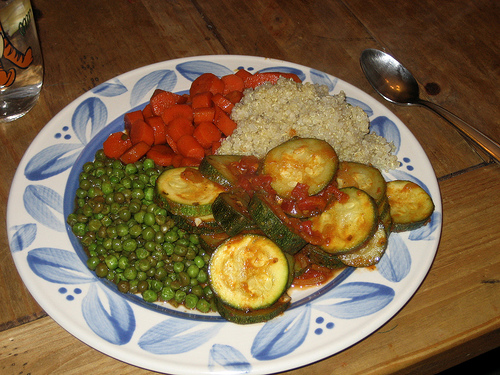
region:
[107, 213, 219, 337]
the peas are green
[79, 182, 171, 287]
the peas are green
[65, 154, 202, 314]
the peas are green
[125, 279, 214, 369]
the peas are green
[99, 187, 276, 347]
the peas are green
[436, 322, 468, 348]
edge of a table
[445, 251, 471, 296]
part of a table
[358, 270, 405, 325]
edge of a plate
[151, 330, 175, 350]
part of a plate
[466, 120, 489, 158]
part of a handle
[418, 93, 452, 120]
part of a spoon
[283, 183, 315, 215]
part of some tomato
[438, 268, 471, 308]
part of a table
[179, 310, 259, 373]
the plate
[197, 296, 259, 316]
the plate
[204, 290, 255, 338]
the plate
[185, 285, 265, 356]
the plate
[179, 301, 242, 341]
the plate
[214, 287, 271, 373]
the plate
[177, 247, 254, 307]
the plate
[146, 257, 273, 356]
the plate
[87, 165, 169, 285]
Green peas on plate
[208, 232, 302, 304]
Cut up zucchini on plate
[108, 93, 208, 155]
Cut up carrot on plate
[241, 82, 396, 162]
Brown grain rice on plate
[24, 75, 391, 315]
Blue floral pattern on white plate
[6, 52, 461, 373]
Blue and white plate on wooden table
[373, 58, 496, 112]
Metal spoon on wood table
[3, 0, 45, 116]
Glass jar with Tigger on it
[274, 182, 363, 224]
Cut up tomato sauce on zucchini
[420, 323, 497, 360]
Edge of wooden table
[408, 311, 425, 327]
the table is wooden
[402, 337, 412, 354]
the table is wooden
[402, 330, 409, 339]
the table is wooden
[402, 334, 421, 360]
the table is wooden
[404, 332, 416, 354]
the table is wooden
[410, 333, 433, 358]
the table is wooden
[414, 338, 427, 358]
the table is wooden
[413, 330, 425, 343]
the table is wooden